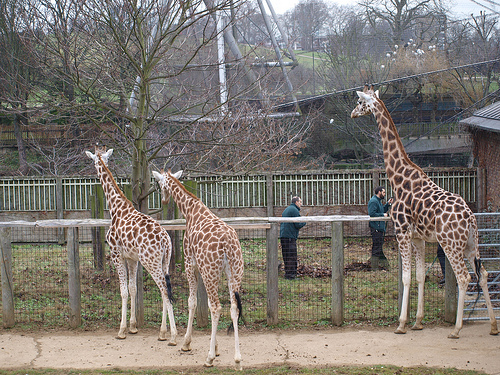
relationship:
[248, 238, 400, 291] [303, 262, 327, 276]
ground has leaves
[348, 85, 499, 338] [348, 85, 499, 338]
giraffe in giraffe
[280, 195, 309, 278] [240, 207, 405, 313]
person behind fence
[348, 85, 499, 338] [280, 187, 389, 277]
giraffe by men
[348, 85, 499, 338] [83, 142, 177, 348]
giraffe by another giraffe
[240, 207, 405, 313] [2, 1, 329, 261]
fence in front of tree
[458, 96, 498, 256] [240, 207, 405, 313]
building by fence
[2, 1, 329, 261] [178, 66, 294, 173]
tree has no leaves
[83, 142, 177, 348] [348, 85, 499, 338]
giraffe in giraffe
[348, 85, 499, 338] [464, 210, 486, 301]
giraffe has a tail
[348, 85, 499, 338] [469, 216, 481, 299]
giraffe has a black tail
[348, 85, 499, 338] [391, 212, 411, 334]
giraffe has a front leg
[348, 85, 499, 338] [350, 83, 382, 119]
giraffe has a head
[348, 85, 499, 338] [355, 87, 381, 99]
giraffe has ears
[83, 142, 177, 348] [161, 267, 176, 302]
giraffe has a tail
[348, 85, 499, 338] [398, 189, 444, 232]
giraffe has a pattern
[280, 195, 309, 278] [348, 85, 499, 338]
person keeper for giraffe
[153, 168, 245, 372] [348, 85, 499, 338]
giraffe in giraffe